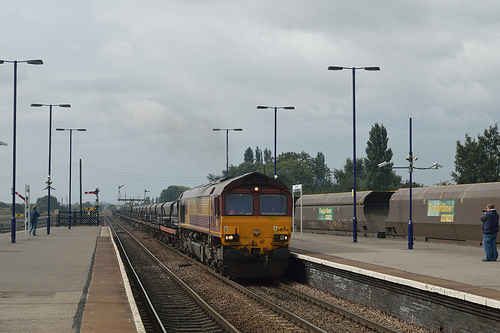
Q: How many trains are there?
A: One.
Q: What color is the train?
A: Yellow and black.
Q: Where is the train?
A: On the tracks.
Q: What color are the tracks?
A: Brown.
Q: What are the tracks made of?
A: Metal.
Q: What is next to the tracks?
A: Gravel.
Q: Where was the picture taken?
A: At the railroad tracks.